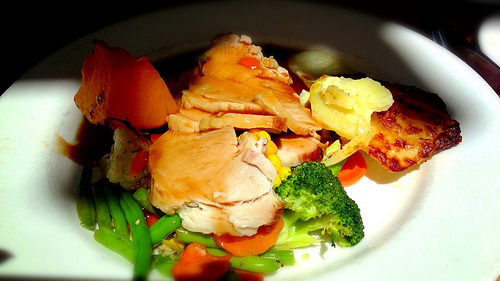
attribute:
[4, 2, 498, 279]
plate — white, circular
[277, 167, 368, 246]
broccoli — green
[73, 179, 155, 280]
beans — green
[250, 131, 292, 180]
corn — yellow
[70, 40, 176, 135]
carrot — orange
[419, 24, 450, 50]
fork — peeping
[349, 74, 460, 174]
potatoes — burnt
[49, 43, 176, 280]
vegetables — colorful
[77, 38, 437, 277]
food — burnt, healthy, identified